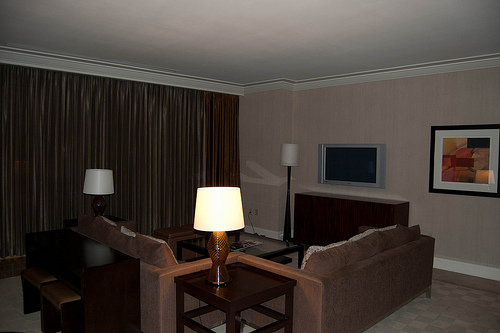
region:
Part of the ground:
[440, 298, 470, 325]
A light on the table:
[191, 182, 249, 291]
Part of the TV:
[346, 158, 366, 176]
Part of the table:
[246, 279, 261, 289]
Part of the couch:
[151, 269, 166, 303]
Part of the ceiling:
[153, 24, 231, 49]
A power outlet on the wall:
[251, 206, 260, 217]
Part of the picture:
[428, 125, 448, 157]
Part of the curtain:
[111, 123, 188, 166]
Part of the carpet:
[5, 294, 16, 324]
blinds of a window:
[202, 88, 259, 192]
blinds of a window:
[166, 103, 210, 181]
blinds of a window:
[166, 196, 181, 234]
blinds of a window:
[137, 86, 149, 146]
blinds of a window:
[119, 176, 146, 227]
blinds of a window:
[95, 89, 133, 153]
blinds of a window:
[30, 82, 82, 156]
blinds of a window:
[32, 172, 63, 236]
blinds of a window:
[7, 93, 51, 173]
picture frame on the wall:
[422, 112, 499, 206]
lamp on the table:
[197, 187, 237, 289]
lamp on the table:
[67, 154, 114, 221]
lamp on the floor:
[273, 137, 299, 244]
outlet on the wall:
[249, 203, 260, 214]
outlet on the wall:
[242, 205, 252, 220]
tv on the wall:
[302, 132, 385, 187]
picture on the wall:
[420, 123, 497, 195]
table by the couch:
[180, 258, 282, 332]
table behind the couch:
[10, 225, 121, 327]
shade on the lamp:
[272, 141, 301, 172]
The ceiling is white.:
[187, 19, 292, 54]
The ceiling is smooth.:
[173, 13, 313, 65]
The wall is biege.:
[324, 100, 408, 136]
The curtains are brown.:
[14, 97, 189, 167]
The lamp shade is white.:
[83, 165, 116, 199]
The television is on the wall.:
[312, 137, 394, 192]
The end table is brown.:
[176, 257, 299, 331]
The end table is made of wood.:
[174, 255, 301, 332]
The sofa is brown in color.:
[314, 232, 435, 330]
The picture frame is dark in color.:
[426, 121, 499, 202]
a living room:
[23, 88, 467, 319]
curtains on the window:
[6, 68, 237, 240]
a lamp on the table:
[85, 170, 119, 221]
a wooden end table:
[186, 262, 282, 329]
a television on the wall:
[317, 145, 382, 185]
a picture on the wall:
[433, 128, 497, 193]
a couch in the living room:
[248, 238, 449, 303]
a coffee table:
[183, 225, 289, 265]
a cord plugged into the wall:
[245, 208, 257, 227]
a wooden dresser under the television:
[296, 191, 384, 225]